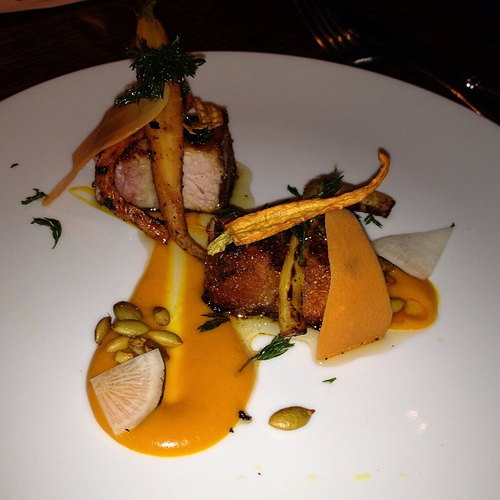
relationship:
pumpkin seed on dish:
[269, 407, 315, 429] [1, 51, 498, 498]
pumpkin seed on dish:
[153, 305, 171, 328] [1, 51, 498, 498]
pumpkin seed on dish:
[111, 317, 151, 338] [1, 51, 498, 498]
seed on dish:
[148, 327, 184, 348] [1, 51, 498, 498]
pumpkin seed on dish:
[94, 316, 114, 343] [1, 51, 498, 498]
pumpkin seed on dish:
[113, 301, 141, 321] [1, 51, 498, 498]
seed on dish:
[388, 296, 407, 314] [1, 51, 498, 498]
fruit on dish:
[87, 346, 170, 433] [1, 51, 498, 498]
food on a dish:
[110, 24, 418, 436] [1, 51, 498, 498]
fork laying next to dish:
[317, 44, 494, 146] [1, 51, 498, 498]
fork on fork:
[310, 21, 499, 124] [299, 3, 411, 83]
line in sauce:
[150, 240, 192, 415] [107, 223, 264, 450]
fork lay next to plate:
[310, 21, 499, 124] [220, 49, 472, 271]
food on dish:
[41, 24, 457, 457] [1, 51, 498, 498]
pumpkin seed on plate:
[94, 316, 114, 343] [243, 50, 486, 151]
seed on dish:
[105, 334, 130, 354] [1, 51, 498, 498]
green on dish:
[306, 357, 351, 395] [1, 51, 498, 498]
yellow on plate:
[343, 260, 373, 305] [293, 66, 358, 147]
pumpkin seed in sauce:
[153, 305, 171, 328] [82, 209, 256, 459]